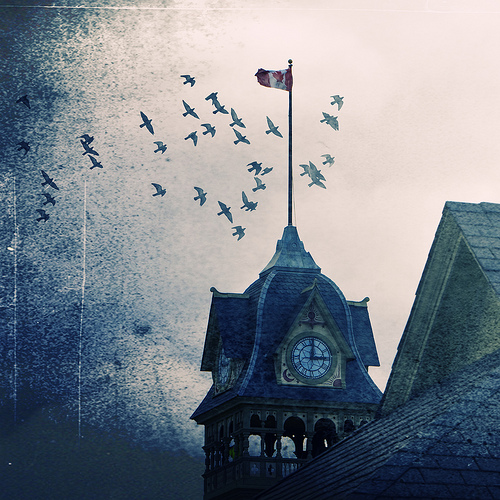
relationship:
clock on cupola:
[280, 297, 342, 388] [184, 225, 390, 419]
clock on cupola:
[206, 339, 241, 390] [184, 225, 390, 419]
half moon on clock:
[282, 366, 296, 383] [254, 316, 371, 424]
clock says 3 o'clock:
[280, 297, 342, 388] [308, 340, 329, 365]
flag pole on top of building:
[254, 51, 296, 222] [195, 200, 499, 497]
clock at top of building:
[280, 297, 342, 388] [187, 225, 387, 500]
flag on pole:
[253, 68, 295, 93] [278, 167, 300, 223]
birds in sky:
[10, 62, 357, 247] [24, 7, 493, 305]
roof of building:
[374, 196, 499, 423] [258, 199, 499, 500]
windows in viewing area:
[187, 392, 364, 463] [201, 403, 357, 497]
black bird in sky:
[139, 180, 172, 214] [116, 229, 166, 281]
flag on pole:
[253, 68, 295, 93] [283, 53, 293, 227]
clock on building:
[290, 335, 333, 380] [187, 225, 387, 500]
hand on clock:
[309, 334, 315, 361] [286, 331, 337, 382]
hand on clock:
[308, 353, 330, 360] [286, 331, 337, 382]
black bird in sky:
[37, 166, 61, 191] [2, 0, 498, 498]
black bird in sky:
[37, 190, 58, 208] [2, 0, 498, 498]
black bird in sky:
[32, 207, 52, 224] [2, 0, 498, 498]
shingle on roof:
[450, 429, 493, 445] [370, 200, 500, 423]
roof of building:
[370, 200, 500, 423] [269, 200, 499, 498]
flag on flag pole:
[253, 57, 295, 231] [287, 59, 294, 226]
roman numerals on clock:
[292, 336, 332, 375] [284, 330, 339, 386]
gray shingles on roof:
[371, 422, 480, 484] [315, 357, 496, 498]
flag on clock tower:
[253, 68, 295, 93] [193, 224, 384, 498]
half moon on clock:
[283, 368, 295, 382] [284, 330, 339, 386]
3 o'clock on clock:
[305, 336, 331, 365] [290, 335, 333, 380]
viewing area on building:
[209, 409, 361, 479] [187, 225, 387, 500]